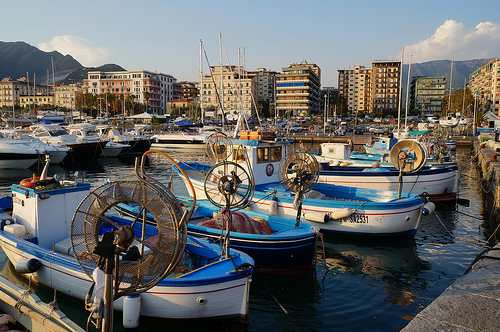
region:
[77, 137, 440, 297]
black fans on boats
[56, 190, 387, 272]
blue bed of boat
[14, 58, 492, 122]
brown buildings in distance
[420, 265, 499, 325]
sidewalk near water is grey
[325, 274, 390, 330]
water is dark blue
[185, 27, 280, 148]
tall masts on boats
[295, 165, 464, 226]
red stripes on boats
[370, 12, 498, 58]
blue and white sky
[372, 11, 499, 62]
white and puffy clouds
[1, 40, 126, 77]
green mountain in distance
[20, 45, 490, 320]
photograph taken at a city pier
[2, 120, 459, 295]
row of blue and white boats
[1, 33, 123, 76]
mountains in the distance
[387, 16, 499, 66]
large white fluffy cloud above mountain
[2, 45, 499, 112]
tall city buildings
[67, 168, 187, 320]
large fans on the boat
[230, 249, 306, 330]
rope used to anchor boat to pier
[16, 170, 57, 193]
orange life saving ring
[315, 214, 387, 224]
black lettering on side of boat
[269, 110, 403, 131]
cars parked in a parking lot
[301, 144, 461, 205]
boat in the water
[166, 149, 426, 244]
boat in the water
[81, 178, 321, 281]
boat in the water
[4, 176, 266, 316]
boat in the water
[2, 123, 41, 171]
boat in the water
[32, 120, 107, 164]
boat in the water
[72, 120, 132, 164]
boat in the water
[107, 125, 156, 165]
boat in the water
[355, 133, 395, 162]
boat in the water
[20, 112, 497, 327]
The boats are sitting in the water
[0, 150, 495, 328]
The boats are at a marina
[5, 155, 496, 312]
The boats were parked by their owners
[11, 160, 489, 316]
The boats are in a river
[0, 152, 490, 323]
The boats are parked here for safety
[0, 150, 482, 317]
The boats are parked in the sunshine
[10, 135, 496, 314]
The boats are all lined up together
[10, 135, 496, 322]
The boats are in a marina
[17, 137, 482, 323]
The boats are all parked together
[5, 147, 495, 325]
The boats are guarded by the Marina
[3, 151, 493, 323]
Some boats are used for fishing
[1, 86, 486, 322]
The boats are parked close to the city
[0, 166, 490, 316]
The boats are floating in a river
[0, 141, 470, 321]
The boats are taken care of well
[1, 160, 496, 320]
The boats are all parked legally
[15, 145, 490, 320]
The boats are parked in the sunshine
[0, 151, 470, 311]
The boats are in shallow water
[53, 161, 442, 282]
Boats in the water.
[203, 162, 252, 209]
Fan on the boat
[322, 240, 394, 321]
Water is dark.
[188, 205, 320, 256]
the boat is blue.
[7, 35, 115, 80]
the mountains are in the background.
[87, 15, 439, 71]
The sky is clear and blue.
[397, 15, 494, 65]
White clouds in the sky.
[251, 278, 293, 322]
rope hanging from the boat.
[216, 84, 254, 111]
Windows on the building.